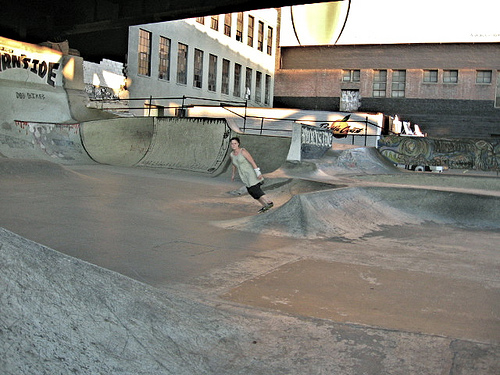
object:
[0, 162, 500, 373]
ground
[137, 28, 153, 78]
window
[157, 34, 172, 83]
window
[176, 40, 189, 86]
window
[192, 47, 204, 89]
window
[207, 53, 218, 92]
window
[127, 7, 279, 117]
building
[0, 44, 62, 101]
painting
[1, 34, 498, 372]
skate park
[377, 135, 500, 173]
graffiti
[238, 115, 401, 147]
railings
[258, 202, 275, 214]
skateboard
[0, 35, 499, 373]
track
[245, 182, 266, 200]
pants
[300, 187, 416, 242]
ramp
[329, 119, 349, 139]
fruit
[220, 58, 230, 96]
windows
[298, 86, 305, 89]
brick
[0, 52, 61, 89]
name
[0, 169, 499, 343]
gray square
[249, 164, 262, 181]
wristband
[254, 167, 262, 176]
wrist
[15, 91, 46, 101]
sign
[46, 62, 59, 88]
black letters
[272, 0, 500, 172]
building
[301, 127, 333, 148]
words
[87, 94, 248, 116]
railing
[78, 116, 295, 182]
ramp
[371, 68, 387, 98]
windows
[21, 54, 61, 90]
word: side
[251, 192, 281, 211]
skating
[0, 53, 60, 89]
words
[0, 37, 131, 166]
wall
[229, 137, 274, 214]
skateboarder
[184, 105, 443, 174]
trailer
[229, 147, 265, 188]
top